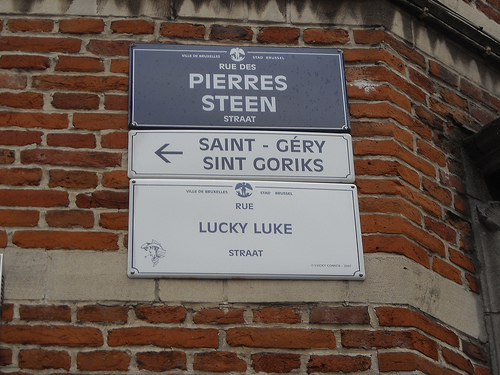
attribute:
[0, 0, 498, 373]
building — brick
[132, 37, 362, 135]
sign — small, white, blue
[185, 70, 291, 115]
lettering — white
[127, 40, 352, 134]
sign — gray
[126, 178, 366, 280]
sign — white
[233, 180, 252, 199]
emblem — of eagle 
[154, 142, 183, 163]
arrow — gray, blue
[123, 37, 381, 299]
sign — white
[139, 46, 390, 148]
sign — dark blue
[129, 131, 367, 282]
borders — gray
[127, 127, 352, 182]
sign — white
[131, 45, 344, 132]
sign — gray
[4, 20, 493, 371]
wall — red, brick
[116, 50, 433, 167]
sign — white, blue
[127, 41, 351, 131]
lettering — gray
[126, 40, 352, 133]
border — white